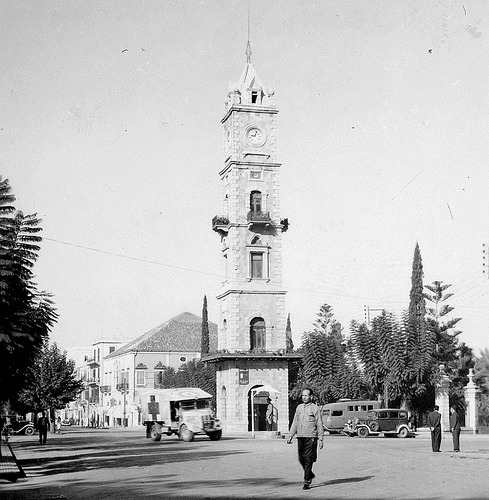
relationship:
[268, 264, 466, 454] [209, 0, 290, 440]
trees behind building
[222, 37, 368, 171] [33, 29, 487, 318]
clouds in sky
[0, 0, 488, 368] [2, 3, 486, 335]
clouds in sky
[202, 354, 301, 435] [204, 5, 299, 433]
story on tower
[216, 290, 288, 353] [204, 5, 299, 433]
story on tower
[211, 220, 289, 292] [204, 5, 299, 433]
story on tower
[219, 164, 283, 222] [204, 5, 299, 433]
story on tower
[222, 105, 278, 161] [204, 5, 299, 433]
story on tower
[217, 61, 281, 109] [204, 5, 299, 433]
story on tower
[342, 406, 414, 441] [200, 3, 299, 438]
car beside building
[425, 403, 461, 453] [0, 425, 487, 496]
men talk on road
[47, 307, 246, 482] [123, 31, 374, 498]
buildings behind tower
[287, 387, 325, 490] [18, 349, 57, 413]
person under tree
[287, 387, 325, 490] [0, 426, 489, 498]
person crosses street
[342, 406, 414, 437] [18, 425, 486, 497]
car on road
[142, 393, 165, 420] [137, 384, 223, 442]
cross on medical truck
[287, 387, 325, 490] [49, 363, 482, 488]
person on road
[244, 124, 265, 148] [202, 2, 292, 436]
round clock on tower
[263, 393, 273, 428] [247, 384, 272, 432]
guard at doorway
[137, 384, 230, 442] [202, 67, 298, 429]
medical truck by building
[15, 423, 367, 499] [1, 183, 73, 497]
shadows of trees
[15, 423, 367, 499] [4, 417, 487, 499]
shadows on ground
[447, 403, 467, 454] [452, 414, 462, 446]
man in suit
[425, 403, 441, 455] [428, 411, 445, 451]
men in suit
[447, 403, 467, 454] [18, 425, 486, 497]
man on road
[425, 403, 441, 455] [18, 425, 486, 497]
men on road